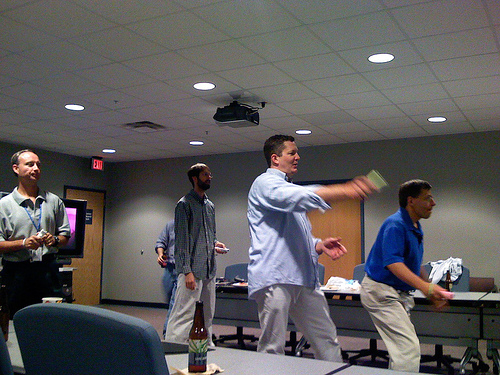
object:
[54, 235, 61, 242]
watch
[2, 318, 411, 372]
table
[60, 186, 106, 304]
door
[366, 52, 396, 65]
light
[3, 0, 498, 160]
ceiling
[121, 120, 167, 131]
air vent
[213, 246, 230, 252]
wii control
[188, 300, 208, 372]
bottle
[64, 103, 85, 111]
light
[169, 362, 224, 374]
napkin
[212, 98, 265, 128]
protector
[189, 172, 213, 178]
glasses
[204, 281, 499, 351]
table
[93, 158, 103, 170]
sign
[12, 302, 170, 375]
chair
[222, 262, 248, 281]
chair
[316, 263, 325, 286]
chair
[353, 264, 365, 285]
chair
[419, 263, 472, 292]
chair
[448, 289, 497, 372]
table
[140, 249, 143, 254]
protector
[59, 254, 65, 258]
door knob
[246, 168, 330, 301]
shirt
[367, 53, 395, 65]
light fixture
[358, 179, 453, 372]
man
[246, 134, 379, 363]
man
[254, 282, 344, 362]
pants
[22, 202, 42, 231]
lanyard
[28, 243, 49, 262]
card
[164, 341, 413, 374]
table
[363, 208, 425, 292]
shirt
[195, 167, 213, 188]
face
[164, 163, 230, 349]
man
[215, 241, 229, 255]
man's hand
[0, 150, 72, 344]
man